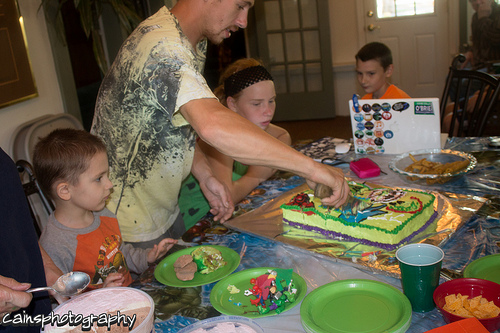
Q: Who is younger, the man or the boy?
A: The boy is younger than the man.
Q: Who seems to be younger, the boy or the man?
A: The boy is younger than the man.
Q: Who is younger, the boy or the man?
A: The boy is younger than the man.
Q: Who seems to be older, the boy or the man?
A: The man is older than the boy.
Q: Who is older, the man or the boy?
A: The man is older than the boy.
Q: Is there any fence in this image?
A: No, there are no fences.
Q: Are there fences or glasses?
A: No, there are no fences or glasses.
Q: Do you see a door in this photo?
A: Yes, there is a door.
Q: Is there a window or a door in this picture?
A: Yes, there is a door.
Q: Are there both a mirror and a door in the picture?
A: No, there is a door but no mirrors.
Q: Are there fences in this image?
A: No, there are no fences.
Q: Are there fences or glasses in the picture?
A: No, there are no fences or glasses.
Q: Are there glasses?
A: No, there are no glasses.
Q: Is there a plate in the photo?
A: Yes, there is a plate.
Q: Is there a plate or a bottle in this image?
A: Yes, there is a plate.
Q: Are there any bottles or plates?
A: Yes, there is a plate.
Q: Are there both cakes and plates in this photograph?
A: Yes, there are both a plate and a cake.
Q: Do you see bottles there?
A: No, there are no bottles.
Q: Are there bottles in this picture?
A: No, there are no bottles.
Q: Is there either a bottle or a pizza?
A: No, there are no bottles or pizzas.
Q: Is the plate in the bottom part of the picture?
A: Yes, the plate is in the bottom of the image.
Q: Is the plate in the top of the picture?
A: No, the plate is in the bottom of the image.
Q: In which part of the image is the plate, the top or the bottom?
A: The plate is in the bottom of the image.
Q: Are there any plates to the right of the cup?
A: Yes, there is a plate to the right of the cup.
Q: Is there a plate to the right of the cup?
A: Yes, there is a plate to the right of the cup.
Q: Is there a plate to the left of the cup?
A: No, the plate is to the right of the cup.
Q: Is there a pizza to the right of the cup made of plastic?
A: No, there is a plate to the right of the cup.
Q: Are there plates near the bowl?
A: Yes, there is a plate near the bowl.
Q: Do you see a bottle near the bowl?
A: No, there is a plate near the bowl.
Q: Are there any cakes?
A: Yes, there is a cake.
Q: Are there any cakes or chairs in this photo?
A: Yes, there is a cake.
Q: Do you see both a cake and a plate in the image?
A: Yes, there are both a cake and a plate.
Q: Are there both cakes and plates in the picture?
A: Yes, there are both a cake and a plate.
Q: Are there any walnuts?
A: No, there are no walnuts.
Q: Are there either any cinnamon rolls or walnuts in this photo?
A: No, there are no walnuts or cinnamon rolls.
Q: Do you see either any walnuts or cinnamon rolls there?
A: No, there are no walnuts or cinnamon rolls.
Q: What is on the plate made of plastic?
A: The cake is on the plate.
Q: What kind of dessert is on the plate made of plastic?
A: The dessert is a cake.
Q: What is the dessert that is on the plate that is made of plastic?
A: The dessert is a cake.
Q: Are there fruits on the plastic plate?
A: No, there is a cake on the plate.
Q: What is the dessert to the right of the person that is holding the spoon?
A: The dessert is a cake.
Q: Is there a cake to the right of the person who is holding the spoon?
A: Yes, there is a cake to the right of the person.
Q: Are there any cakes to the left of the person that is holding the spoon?
A: No, the cake is to the right of the person.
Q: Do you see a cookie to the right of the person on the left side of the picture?
A: No, there is a cake to the right of the person.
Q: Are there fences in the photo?
A: No, there are no fences.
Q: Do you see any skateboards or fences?
A: No, there are no fences or skateboards.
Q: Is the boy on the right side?
A: Yes, the boy is on the right of the image.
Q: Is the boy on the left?
A: No, the boy is on the right of the image.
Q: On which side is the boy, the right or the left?
A: The boy is on the right of the image.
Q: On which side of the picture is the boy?
A: The boy is on the right of the image.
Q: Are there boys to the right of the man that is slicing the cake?
A: Yes, there is a boy to the right of the man.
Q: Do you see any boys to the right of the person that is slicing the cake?
A: Yes, there is a boy to the right of the man.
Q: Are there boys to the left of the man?
A: No, the boy is to the right of the man.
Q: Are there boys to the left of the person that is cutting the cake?
A: No, the boy is to the right of the man.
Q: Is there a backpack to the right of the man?
A: No, there is a boy to the right of the man.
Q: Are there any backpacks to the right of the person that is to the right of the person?
A: No, there is a boy to the right of the man.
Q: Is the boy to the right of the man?
A: Yes, the boy is to the right of the man.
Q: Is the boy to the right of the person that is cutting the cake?
A: Yes, the boy is to the right of the man.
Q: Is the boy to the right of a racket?
A: No, the boy is to the right of the man.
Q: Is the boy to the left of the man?
A: No, the boy is to the right of the man.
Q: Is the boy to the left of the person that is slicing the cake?
A: No, the boy is to the right of the man.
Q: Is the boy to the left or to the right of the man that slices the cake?
A: The boy is to the right of the man.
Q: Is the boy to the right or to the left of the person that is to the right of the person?
A: The boy is to the right of the man.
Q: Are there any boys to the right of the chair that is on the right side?
A: No, the boy is to the left of the chair.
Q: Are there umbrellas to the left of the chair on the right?
A: No, there is a boy to the left of the chair.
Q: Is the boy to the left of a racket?
A: No, the boy is to the left of the chair.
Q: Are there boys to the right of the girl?
A: Yes, there is a boy to the right of the girl.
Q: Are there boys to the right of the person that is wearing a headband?
A: Yes, there is a boy to the right of the girl.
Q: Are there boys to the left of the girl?
A: No, the boy is to the right of the girl.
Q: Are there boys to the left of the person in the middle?
A: No, the boy is to the right of the girl.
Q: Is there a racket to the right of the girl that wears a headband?
A: No, there is a boy to the right of the girl.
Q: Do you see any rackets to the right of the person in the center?
A: No, there is a boy to the right of the girl.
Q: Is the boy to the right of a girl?
A: Yes, the boy is to the right of a girl.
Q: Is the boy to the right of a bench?
A: No, the boy is to the right of a girl.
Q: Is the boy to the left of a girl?
A: No, the boy is to the right of a girl.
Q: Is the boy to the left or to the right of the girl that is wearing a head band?
A: The boy is to the right of the girl.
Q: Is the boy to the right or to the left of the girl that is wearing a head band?
A: The boy is to the right of the girl.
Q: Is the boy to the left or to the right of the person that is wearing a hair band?
A: The boy is to the right of the girl.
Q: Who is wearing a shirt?
A: The boy is wearing a shirt.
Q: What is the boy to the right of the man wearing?
A: The boy is wearing a shirt.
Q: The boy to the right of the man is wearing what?
A: The boy is wearing a shirt.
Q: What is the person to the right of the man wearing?
A: The boy is wearing a shirt.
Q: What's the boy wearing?
A: The boy is wearing a shirt.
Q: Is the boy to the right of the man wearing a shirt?
A: Yes, the boy is wearing a shirt.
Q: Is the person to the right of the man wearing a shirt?
A: Yes, the boy is wearing a shirt.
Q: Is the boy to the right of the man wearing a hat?
A: No, the boy is wearing a shirt.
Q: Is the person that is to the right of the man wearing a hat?
A: No, the boy is wearing a shirt.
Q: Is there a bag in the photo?
A: No, there are no bags.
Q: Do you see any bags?
A: No, there are no bags.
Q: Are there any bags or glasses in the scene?
A: No, there are no bags or glasses.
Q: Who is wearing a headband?
A: The girl is wearing a headband.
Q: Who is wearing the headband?
A: The girl is wearing a headband.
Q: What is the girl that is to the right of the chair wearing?
A: The girl is wearing a headband.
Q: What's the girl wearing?
A: The girl is wearing a headband.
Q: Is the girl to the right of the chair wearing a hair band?
A: Yes, the girl is wearing a hair band.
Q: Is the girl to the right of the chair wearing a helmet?
A: No, the girl is wearing a hair band.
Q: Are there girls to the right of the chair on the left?
A: Yes, there is a girl to the right of the chair.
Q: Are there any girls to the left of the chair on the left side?
A: No, the girl is to the right of the chair.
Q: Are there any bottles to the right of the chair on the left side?
A: No, there is a girl to the right of the chair.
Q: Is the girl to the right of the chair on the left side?
A: Yes, the girl is to the right of the chair.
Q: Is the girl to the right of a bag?
A: No, the girl is to the right of the chair.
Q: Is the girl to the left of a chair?
A: No, the girl is to the right of a chair.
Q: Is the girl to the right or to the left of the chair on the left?
A: The girl is to the right of the chair.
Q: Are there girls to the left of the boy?
A: Yes, there is a girl to the left of the boy.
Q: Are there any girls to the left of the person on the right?
A: Yes, there is a girl to the left of the boy.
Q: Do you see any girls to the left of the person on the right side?
A: Yes, there is a girl to the left of the boy.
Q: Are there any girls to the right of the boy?
A: No, the girl is to the left of the boy.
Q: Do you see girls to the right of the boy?
A: No, the girl is to the left of the boy.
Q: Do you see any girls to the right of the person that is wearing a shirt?
A: No, the girl is to the left of the boy.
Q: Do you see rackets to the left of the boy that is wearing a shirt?
A: No, there is a girl to the left of the boy.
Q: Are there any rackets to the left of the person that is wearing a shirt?
A: No, there is a girl to the left of the boy.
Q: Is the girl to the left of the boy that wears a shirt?
A: Yes, the girl is to the left of the boy.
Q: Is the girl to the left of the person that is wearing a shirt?
A: Yes, the girl is to the left of the boy.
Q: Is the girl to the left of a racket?
A: No, the girl is to the left of the boy.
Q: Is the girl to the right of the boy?
A: No, the girl is to the left of the boy.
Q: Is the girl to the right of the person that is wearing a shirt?
A: No, the girl is to the left of the boy.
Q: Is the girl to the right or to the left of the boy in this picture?
A: The girl is to the left of the boy.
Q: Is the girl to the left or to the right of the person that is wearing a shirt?
A: The girl is to the left of the boy.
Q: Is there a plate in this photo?
A: Yes, there is a plate.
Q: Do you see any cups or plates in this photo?
A: Yes, there is a plate.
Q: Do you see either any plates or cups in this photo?
A: Yes, there is a plate.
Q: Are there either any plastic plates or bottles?
A: Yes, there is a plastic plate.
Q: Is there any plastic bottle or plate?
A: Yes, there is a plastic plate.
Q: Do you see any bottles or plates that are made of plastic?
A: Yes, the plate is made of plastic.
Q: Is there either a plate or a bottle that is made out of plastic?
A: Yes, the plate is made of plastic.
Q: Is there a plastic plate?
A: Yes, there is a plate that is made of plastic.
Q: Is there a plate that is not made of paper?
A: Yes, there is a plate that is made of plastic.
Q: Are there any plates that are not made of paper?
A: Yes, there is a plate that is made of plastic.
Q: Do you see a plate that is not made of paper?
A: Yes, there is a plate that is made of plastic.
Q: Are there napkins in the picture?
A: No, there are no napkins.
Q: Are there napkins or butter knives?
A: No, there are no napkins or butter knives.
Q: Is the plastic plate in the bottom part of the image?
A: Yes, the plate is in the bottom of the image.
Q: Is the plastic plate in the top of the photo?
A: No, the plate is in the bottom of the image.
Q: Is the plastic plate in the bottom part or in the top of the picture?
A: The plate is in the bottom of the image.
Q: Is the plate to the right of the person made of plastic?
A: Yes, the plate is made of plastic.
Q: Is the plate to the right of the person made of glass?
A: No, the plate is made of plastic.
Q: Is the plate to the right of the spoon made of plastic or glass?
A: The plate is made of plastic.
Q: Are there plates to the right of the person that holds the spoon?
A: Yes, there is a plate to the right of the person.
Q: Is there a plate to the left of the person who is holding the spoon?
A: No, the plate is to the right of the person.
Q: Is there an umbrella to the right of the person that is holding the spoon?
A: No, there is a plate to the right of the person.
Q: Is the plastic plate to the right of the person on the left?
A: Yes, the plate is to the right of the person.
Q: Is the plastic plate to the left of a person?
A: No, the plate is to the right of a person.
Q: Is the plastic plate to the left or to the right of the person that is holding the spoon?
A: The plate is to the right of the person.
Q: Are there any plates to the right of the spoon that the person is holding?
A: Yes, there is a plate to the right of the spoon.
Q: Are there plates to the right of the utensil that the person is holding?
A: Yes, there is a plate to the right of the spoon.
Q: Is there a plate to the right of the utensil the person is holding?
A: Yes, there is a plate to the right of the spoon.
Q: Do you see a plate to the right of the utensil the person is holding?
A: Yes, there is a plate to the right of the spoon.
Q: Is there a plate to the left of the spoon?
A: No, the plate is to the right of the spoon.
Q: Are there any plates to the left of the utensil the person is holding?
A: No, the plate is to the right of the spoon.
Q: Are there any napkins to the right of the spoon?
A: No, there is a plate to the right of the spoon.